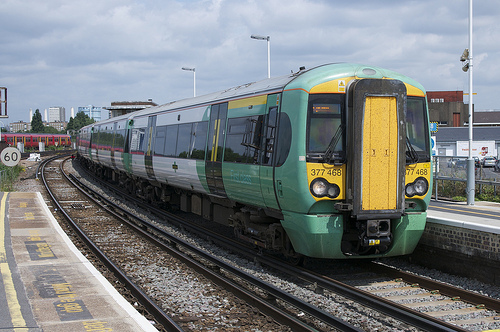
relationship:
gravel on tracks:
[353, 269, 492, 329] [60, 149, 498, 329]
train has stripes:
[76, 61, 436, 262] [75, 103, 207, 195]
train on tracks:
[76, 61, 436, 262] [60, 149, 498, 329]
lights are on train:
[310, 174, 429, 199] [76, 61, 436, 262]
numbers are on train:
[308, 166, 342, 179] [76, 61, 436, 262]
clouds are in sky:
[1, 5, 499, 124] [3, 1, 499, 126]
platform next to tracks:
[426, 197, 499, 264] [60, 149, 498, 329]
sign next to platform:
[430, 117, 438, 177] [426, 197, 499, 264]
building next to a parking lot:
[433, 124, 499, 161] [433, 156, 499, 189]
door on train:
[360, 94, 402, 213] [300, 62, 435, 263]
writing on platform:
[17, 191, 112, 330] [1, 187, 157, 329]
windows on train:
[76, 114, 266, 166] [76, 61, 436, 262]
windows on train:
[1, 135, 66, 145] [1, 129, 72, 151]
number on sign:
[1, 149, 20, 164] [1, 144, 22, 168]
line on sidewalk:
[2, 186, 28, 331] [0, 189, 158, 331]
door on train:
[360, 94, 402, 213] [76, 61, 436, 262]